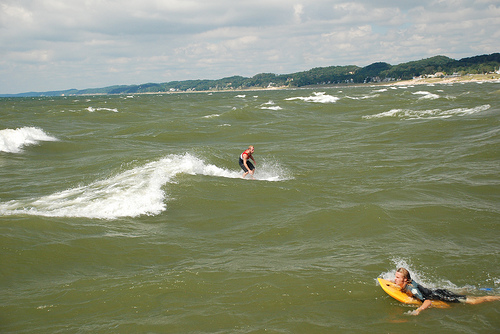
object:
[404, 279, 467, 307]
wetsuit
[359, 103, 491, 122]
waves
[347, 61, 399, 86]
hills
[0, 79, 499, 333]
ocean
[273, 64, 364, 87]
hill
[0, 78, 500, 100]
shoreline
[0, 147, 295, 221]
wave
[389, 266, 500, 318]
man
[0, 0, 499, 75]
cloud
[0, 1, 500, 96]
sky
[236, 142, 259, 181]
man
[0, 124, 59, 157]
wave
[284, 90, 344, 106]
wave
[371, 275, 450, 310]
board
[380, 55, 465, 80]
hillside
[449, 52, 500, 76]
mountains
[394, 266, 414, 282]
blonde hair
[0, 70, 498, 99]
beach